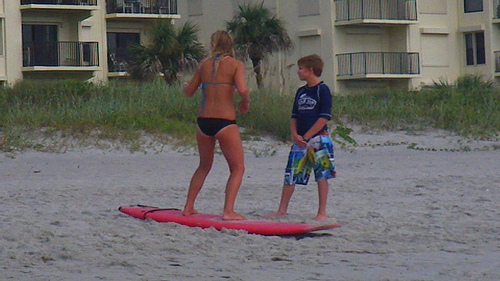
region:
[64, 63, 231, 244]
the sand is grey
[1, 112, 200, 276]
the sand is grey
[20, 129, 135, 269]
the sand is grey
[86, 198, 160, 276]
the sand is grey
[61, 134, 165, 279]
the sand is grey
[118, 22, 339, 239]
the woman wearing a bikini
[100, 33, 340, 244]
the woman standing on a surfboard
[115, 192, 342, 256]
the surfboard is pink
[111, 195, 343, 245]
the surfboard is on the sand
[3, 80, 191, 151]
the grass behind the sand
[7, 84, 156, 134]
the grass is tall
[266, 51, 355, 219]
the young boy is standing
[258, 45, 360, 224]
the young boy is on the sand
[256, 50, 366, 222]
the young boy is wearing shorts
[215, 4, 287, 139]
the palm tree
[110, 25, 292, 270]
lady on a surfboard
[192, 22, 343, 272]
lady on a surfboard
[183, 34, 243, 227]
a girl at beach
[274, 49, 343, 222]
a young boy at beach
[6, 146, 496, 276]
light grey beach sand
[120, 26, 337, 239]
a girl on a surboard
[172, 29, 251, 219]
a girl wearing bikini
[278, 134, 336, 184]
multi colored blue board shorts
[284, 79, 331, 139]
a dark blue t-shirt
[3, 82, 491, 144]
a row of beach grass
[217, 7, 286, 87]
a short tree in distance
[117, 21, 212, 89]
a short tree in distance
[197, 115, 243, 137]
a woman's bathing suit bottoms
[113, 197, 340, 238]
a red surfboard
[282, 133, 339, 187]
boy's colorful swim shorts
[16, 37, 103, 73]
the balcony of a hotel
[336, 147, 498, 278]
part of a beach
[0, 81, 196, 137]
tall green grass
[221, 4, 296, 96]
a tall green tree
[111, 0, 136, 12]
part of a white chair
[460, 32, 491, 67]
the window of a building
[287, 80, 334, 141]
a boy's short sleeve blue shirt